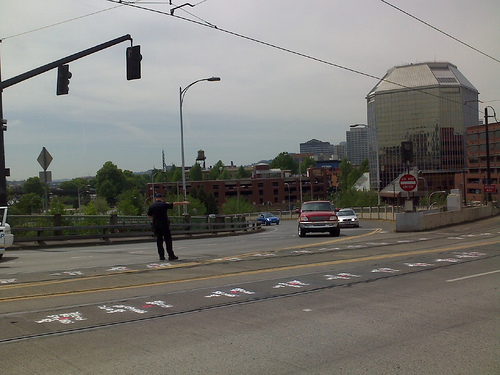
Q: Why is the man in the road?
A: Directing traffic.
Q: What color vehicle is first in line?
A: Red.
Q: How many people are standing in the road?
A: 1.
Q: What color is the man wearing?
A: Black.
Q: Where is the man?
A: In the road.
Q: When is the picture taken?
A: Daytime.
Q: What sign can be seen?
A: Do not enter.